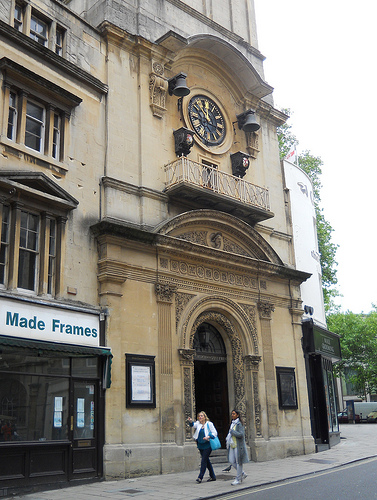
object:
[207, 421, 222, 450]
purse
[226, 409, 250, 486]
woman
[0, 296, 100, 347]
advertisement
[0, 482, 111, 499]
store front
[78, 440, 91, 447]
mail slot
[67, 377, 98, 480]
door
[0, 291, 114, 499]
store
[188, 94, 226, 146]
clock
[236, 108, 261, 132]
bell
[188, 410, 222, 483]
woman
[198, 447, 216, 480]
jeans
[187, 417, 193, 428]
flowers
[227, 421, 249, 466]
clothes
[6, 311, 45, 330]
made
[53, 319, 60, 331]
f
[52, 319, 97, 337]
frames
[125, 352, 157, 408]
frame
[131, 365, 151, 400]
paper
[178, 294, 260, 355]
archway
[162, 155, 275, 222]
balcony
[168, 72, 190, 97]
bell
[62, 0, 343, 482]
building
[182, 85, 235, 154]
clock face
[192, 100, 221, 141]
numbers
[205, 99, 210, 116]
hands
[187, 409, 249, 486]
people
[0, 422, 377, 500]
sidewalk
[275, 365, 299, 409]
sign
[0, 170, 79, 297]
windows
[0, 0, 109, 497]
building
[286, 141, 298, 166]
flag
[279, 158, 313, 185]
roof